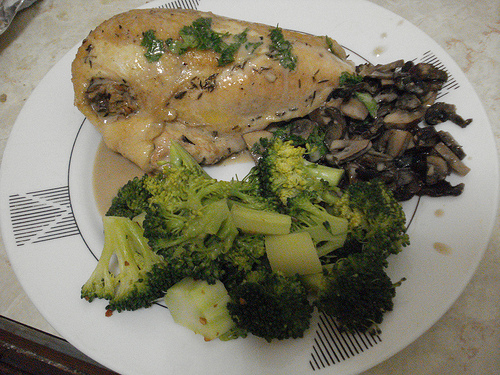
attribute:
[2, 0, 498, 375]
plate — round, white, black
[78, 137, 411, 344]
broccoli — green, steamed, fresh, beautiful, chopped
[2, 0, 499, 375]
table — wooden, white, granite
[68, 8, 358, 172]
chicken — delicious, moist, cooked, grilled, brown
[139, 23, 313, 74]
vegetables — black, fresh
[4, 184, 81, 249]
stripes — black, triangle design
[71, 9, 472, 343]
food — home cooked, healthy, low calories, delicious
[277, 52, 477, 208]
mushrooms — sauteed, delicious, chopped, fried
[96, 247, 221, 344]
pepper flakes — red